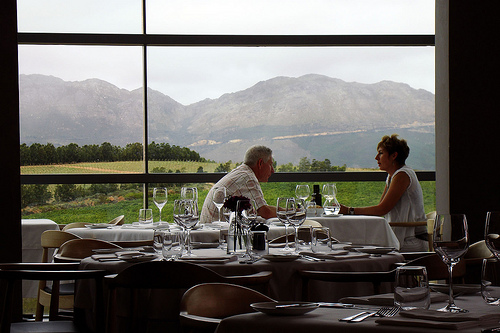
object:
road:
[185, 122, 431, 148]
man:
[200, 145, 275, 219]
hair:
[243, 145, 271, 162]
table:
[308, 216, 402, 251]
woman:
[346, 134, 429, 250]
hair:
[379, 134, 410, 164]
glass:
[294, 185, 309, 208]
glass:
[322, 183, 336, 217]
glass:
[152, 187, 167, 226]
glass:
[180, 185, 198, 213]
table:
[69, 221, 224, 246]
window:
[15, 0, 435, 316]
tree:
[43, 144, 56, 164]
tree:
[100, 142, 113, 162]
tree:
[149, 143, 158, 160]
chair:
[33, 231, 81, 321]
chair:
[52, 240, 120, 323]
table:
[53, 244, 401, 325]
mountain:
[17, 72, 182, 130]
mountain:
[190, 74, 448, 127]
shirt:
[385, 169, 423, 244]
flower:
[238, 198, 252, 211]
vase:
[226, 214, 248, 257]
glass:
[139, 209, 153, 225]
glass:
[310, 226, 332, 255]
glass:
[391, 265, 432, 315]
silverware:
[350, 305, 399, 323]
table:
[213, 284, 496, 333]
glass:
[434, 215, 467, 313]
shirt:
[200, 164, 270, 226]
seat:
[184, 280, 270, 332]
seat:
[299, 248, 467, 290]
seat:
[6, 257, 101, 333]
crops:
[23, 161, 224, 177]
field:
[22, 158, 221, 182]